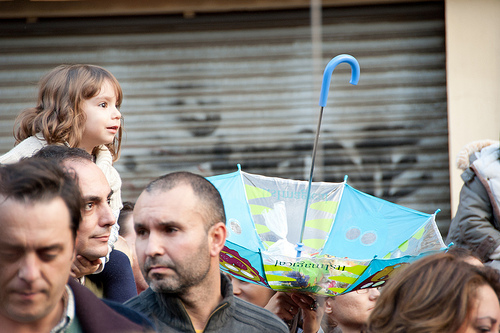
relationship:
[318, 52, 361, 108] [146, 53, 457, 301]
blue handle attached to umbrella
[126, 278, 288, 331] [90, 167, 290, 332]
sweater worn by human